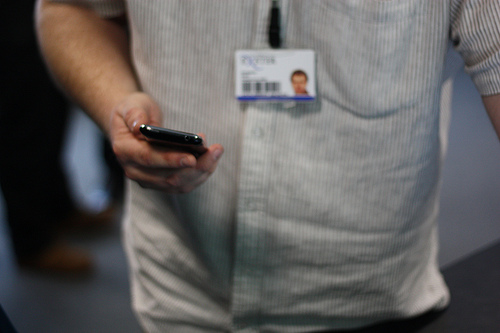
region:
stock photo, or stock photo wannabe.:
[0, 0, 499, 332]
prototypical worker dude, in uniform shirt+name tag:
[27, 0, 497, 330]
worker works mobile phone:
[56, 50, 239, 205]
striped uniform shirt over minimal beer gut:
[126, 0, 498, 332]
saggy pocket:
[299, 0, 434, 118]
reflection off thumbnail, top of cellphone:
[128, 119, 205, 159]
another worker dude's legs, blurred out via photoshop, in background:
[0, 0, 125, 300]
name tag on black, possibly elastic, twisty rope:
[235, 0, 317, 106]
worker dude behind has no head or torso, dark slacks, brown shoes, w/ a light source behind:
[7, 95, 127, 294]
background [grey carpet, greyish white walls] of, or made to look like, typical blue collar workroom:
[0, 44, 498, 330]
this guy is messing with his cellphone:
[13, 8, 464, 317]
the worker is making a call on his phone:
[45, 11, 433, 232]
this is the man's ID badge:
[225, 25, 342, 119]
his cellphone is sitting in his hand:
[85, 84, 227, 209]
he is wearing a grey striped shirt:
[136, 8, 438, 309]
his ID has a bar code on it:
[230, 71, 287, 101]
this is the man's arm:
[25, 16, 227, 206]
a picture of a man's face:
[287, 68, 312, 103]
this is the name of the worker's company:
[238, 49, 278, 71]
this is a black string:
[259, 3, 295, 48]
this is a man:
[135, 42, 487, 308]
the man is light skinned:
[61, 13, 106, 62]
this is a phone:
[136, 117, 205, 152]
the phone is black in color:
[148, 126, 193, 161]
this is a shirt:
[314, 157, 393, 279]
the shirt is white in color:
[279, 178, 343, 263]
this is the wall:
[458, 127, 493, 232]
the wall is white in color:
[466, 131, 487, 209]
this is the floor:
[463, 267, 477, 324]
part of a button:
[241, 110, 281, 155]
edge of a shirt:
[363, 302, 388, 322]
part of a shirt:
[232, 252, 238, 264]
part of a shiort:
[227, 238, 245, 280]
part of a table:
[465, 251, 488, 287]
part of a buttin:
[240, 212, 266, 260]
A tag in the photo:
[228, 47, 321, 102]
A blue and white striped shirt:
[298, 115, 412, 273]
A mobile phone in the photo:
[134, 122, 206, 158]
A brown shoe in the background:
[29, 230, 96, 281]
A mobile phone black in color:
[137, 118, 210, 161]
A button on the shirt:
[248, 122, 272, 140]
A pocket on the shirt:
[320, 14, 402, 117]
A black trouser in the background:
[2, 87, 59, 210]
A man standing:
[40, 0, 430, 322]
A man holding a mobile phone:
[52, 4, 497, 322]